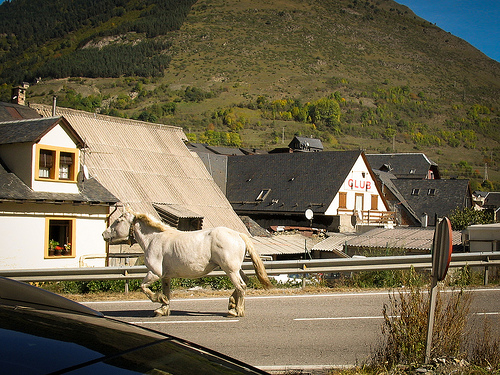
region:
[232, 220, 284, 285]
brown color on white pony's tail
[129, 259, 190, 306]
horse's leg lifted off the floor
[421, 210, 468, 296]
red circular sign on wooden post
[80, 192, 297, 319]
small white horse on the road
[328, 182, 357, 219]
brown windows in building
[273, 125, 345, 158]
house located on the mountain side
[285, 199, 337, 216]
white cable dish on top of roof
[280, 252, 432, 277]
long silver railing at side of road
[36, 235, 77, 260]
flowering red plant in window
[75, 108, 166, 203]
slanted gray roof on house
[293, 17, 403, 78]
the green color grass on the hill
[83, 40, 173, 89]
the bunch of green color trees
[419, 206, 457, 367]
the sign board in the road side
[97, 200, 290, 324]
the white color horse on the road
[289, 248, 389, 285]
the iron seperation on the road side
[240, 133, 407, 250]
the club in the middle of house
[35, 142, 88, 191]
the windows of the house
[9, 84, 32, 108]
the chimney on the top of house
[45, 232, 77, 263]
the plants in the window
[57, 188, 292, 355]
a white horse crossing a road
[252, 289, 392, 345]
white lines painted on a road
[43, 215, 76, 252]
potted flowers sitting in a window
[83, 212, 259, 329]
a white horse standing in a road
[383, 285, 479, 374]
a dead bush next to a road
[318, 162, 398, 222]
a white and tan building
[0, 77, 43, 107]
a chimney on top of a house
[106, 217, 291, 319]
a white horse with long tail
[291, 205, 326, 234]
a satellite dish attached to a building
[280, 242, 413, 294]
a metal guardrail next to a road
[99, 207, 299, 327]
horse running on road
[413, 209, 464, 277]
sign near road is red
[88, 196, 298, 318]
horse is mostly white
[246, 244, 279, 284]
horse has white and brown tail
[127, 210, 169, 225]
horse has tan mane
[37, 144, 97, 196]
window has tan frame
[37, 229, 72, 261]
green and red flower in window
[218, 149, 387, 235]
store has black roof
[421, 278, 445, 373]
red sign on wood post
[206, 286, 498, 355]
road is grey and white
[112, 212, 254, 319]
white horse on street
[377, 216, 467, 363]
sign in green grass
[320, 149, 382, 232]
white building that says club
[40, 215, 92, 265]
plants in a window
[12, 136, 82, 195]
two windows with yellow paint on them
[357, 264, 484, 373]
tall green grass by pole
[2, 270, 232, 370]
black car on road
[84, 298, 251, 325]
shadow on the cement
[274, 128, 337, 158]
house on a hill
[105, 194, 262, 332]
white and yellow mane